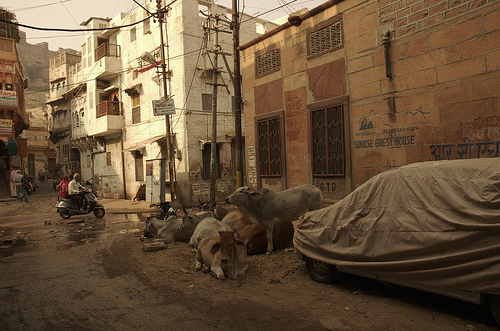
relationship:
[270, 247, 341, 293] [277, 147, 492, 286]
tire under cover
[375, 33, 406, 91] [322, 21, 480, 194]
pipe on wall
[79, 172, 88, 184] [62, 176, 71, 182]
man and woman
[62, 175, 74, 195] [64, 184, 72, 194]
women in outfit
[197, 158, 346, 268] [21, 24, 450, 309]
cow in city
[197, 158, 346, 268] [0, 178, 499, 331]
cow in road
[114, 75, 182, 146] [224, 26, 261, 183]
sign on pole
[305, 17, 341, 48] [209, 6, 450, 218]
window on building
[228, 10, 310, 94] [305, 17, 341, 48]
awning over window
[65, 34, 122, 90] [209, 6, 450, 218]
balcony on building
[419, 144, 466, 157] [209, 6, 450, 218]
graffiti on building